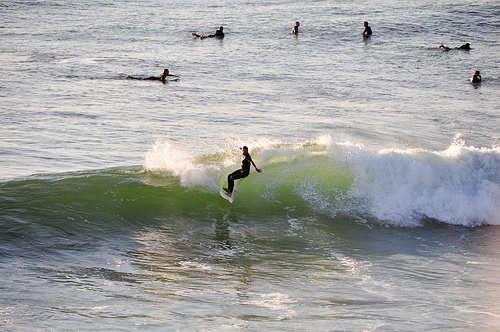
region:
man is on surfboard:
[203, 141, 259, 198]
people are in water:
[133, 12, 493, 104]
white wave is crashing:
[377, 144, 496, 235]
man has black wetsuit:
[228, 149, 253, 189]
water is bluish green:
[242, 138, 316, 213]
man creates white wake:
[144, 149, 211, 191]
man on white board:
[215, 164, 238, 209]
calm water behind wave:
[30, 15, 106, 108]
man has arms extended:
[226, 141, 268, 193]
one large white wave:
[282, 141, 499, 230]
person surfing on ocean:
[207, 134, 266, 212]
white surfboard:
[210, 165, 244, 212]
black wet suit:
[222, 150, 257, 193]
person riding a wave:
[204, 131, 267, 209]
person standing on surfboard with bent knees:
[214, 137, 266, 208]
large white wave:
[300, 128, 498, 238]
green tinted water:
[272, 160, 307, 208]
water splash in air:
[145, 133, 190, 155]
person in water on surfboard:
[115, 58, 185, 90]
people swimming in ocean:
[277, 8, 376, 49]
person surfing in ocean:
[198, 132, 270, 218]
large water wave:
[196, 129, 487, 251]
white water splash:
[131, 133, 193, 167]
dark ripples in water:
[48, 257, 145, 292]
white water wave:
[342, 137, 489, 229]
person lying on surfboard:
[104, 57, 196, 93]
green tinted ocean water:
[272, 151, 324, 193]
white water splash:
[440, 128, 474, 150]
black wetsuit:
[218, 152, 258, 192]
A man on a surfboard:
[206, 140, 262, 207]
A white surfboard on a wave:
[216, 180, 238, 205]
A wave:
[7, 145, 497, 235]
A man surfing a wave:
[208, 135, 270, 204]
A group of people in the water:
[105, 13, 487, 100]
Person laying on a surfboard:
[115, 60, 194, 86]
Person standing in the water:
[287, 18, 307, 43]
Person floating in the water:
[433, 38, 477, 58]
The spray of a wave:
[275, 131, 497, 223]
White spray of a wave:
[300, 140, 495, 222]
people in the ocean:
[133, 28, 481, 127]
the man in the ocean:
[208, 141, 263, 208]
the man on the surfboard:
[220, 143, 252, 208]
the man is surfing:
[210, 138, 265, 199]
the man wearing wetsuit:
[220, 140, 261, 200]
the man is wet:
[217, 139, 257, 214]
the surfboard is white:
[214, 183, 241, 204]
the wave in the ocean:
[27, 138, 497, 253]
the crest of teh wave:
[41, 159, 71, 184]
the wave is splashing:
[314, 131, 494, 236]